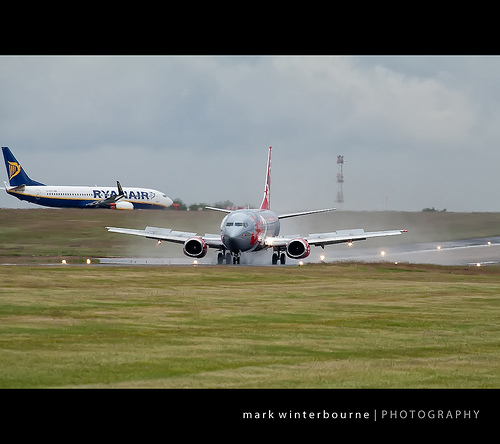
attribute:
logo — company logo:
[5, 155, 24, 185]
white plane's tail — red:
[255, 144, 285, 211]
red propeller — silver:
[288, 236, 307, 256]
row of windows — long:
[45, 190, 95, 199]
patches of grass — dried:
[396, 345, 494, 371]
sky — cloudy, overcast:
[2, 57, 496, 213]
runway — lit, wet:
[51, 236, 499, 268]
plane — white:
[4, 141, 193, 220]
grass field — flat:
[5, 258, 499, 392]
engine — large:
[290, 232, 317, 258]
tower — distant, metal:
[326, 124, 352, 203]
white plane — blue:
[4, 141, 180, 210]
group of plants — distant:
[169, 196, 262, 214]